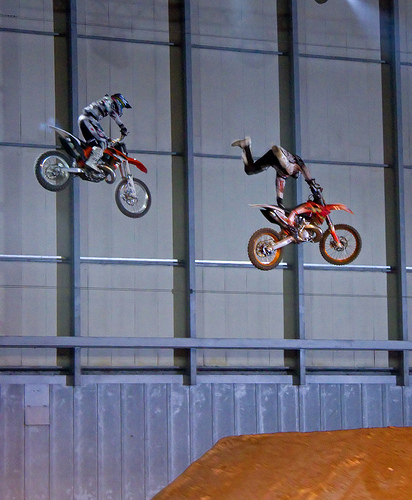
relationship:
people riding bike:
[76, 90, 133, 174] [34, 117, 151, 220]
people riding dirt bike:
[227, 134, 301, 209] [245, 190, 362, 270]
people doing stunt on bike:
[227, 134, 323, 210] [243, 193, 362, 273]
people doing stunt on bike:
[76, 91, 133, 174] [34, 117, 151, 220]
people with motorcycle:
[227, 134, 323, 210] [247, 179, 362, 270]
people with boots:
[76, 91, 133, 174] [84, 147, 105, 179]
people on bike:
[227, 134, 323, 210] [246, 177, 363, 271]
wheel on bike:
[246, 226, 286, 271] [243, 193, 362, 273]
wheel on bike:
[319, 224, 364, 271] [243, 193, 362, 273]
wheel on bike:
[34, 146, 74, 189] [34, 117, 151, 220]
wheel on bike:
[113, 174, 153, 219] [34, 117, 151, 220]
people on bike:
[76, 91, 133, 174] [34, 117, 151, 220]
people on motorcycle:
[227, 134, 323, 210] [247, 179, 362, 270]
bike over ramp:
[246, 177, 363, 271] [143, 424, 410, 498]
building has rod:
[4, 0, 410, 498] [168, 2, 198, 369]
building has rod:
[4, 0, 410, 498] [50, 7, 80, 387]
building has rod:
[4, 0, 410, 498] [274, 7, 304, 384]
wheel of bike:
[319, 224, 362, 266] [34, 117, 151, 220]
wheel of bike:
[246, 226, 286, 271] [246, 177, 363, 271]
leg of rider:
[242, 146, 272, 176] [229, 134, 310, 208]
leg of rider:
[228, 132, 274, 173] [226, 127, 315, 210]